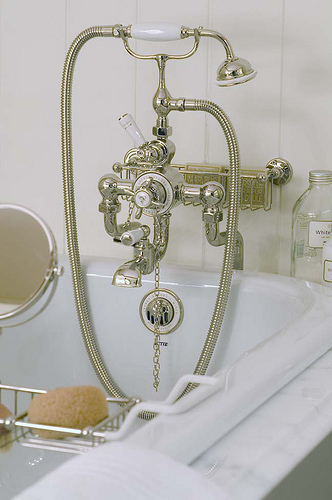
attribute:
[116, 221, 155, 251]
tap — gold, chrome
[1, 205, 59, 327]
mirror — vanity, round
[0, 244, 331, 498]
tub — white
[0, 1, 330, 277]
wall — white, tiled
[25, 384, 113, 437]
sponge — loofah, brown, small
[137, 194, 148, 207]
symbol — logo, blue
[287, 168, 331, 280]
bottle — clear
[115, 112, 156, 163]
handle — white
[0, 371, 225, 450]
rack — tray, silver, metal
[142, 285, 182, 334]
drain — valve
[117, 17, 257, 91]
spigot — handheld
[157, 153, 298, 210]
tray — metal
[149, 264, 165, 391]
chain — long, metal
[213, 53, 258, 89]
head — white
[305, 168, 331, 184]
cap — silver